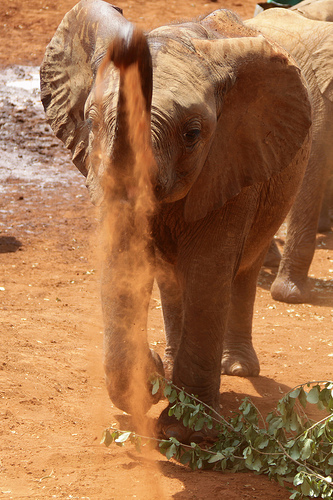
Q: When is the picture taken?
A: Daytime.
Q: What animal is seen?
A: Elephant.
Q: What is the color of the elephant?
A: Grey.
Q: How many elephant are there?
A: 2.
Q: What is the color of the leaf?
A: Green.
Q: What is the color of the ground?
A: Brown.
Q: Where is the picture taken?
A: In Africa.